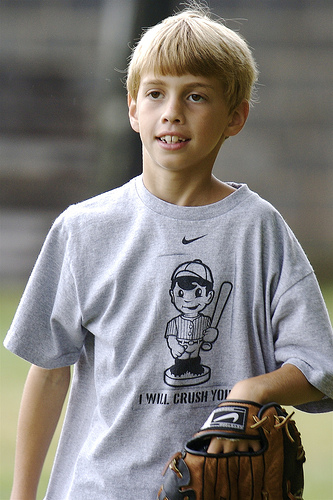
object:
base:
[162, 364, 211, 388]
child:
[164, 257, 219, 380]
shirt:
[0, 173, 333, 499]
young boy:
[0, 2, 333, 500]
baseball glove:
[156, 398, 306, 498]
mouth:
[154, 128, 190, 152]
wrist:
[225, 375, 271, 404]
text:
[137, 385, 233, 405]